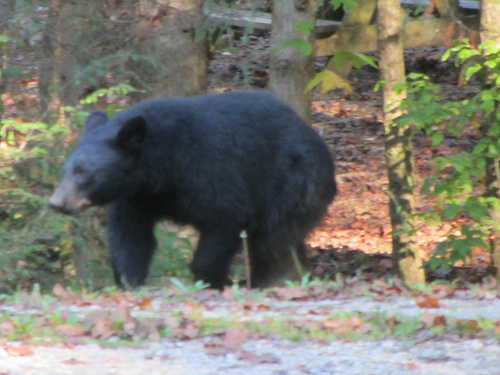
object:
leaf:
[54, 283, 70, 301]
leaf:
[92, 313, 115, 333]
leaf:
[137, 296, 153, 312]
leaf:
[223, 323, 246, 348]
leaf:
[277, 284, 308, 301]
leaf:
[413, 290, 440, 307]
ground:
[0, 0, 500, 375]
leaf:
[261, 35, 313, 57]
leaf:
[454, 48, 479, 67]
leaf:
[472, 88, 497, 112]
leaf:
[471, 137, 489, 154]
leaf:
[465, 195, 489, 219]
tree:
[375, 2, 425, 290]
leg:
[190, 173, 245, 290]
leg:
[109, 204, 157, 292]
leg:
[251, 195, 337, 290]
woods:
[0, 0, 500, 375]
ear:
[84, 110, 108, 136]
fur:
[47, 88, 340, 287]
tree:
[268, 0, 314, 132]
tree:
[124, 0, 210, 100]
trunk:
[376, 0, 428, 286]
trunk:
[268, 0, 311, 125]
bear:
[47, 90, 337, 289]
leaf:
[365, 213, 373, 222]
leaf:
[348, 197, 359, 203]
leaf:
[337, 171, 372, 183]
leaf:
[344, 147, 361, 157]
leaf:
[421, 159, 431, 165]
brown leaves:
[372, 37, 499, 274]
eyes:
[62, 165, 83, 174]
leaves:
[255, 0, 497, 294]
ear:
[117, 115, 146, 150]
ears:
[82, 111, 146, 144]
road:
[0, 277, 500, 375]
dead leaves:
[0, 271, 499, 341]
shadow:
[298, 244, 498, 282]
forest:
[0, 0, 500, 292]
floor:
[0, 0, 499, 375]